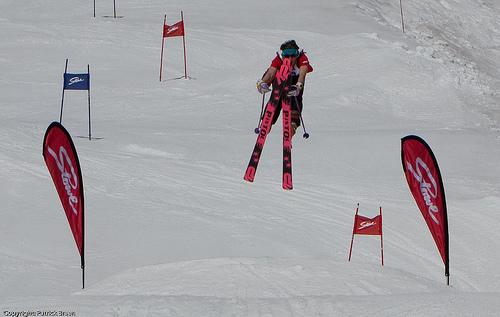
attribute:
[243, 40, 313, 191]
person — jumping, doing tricks, skiing, jumping in air, performing stunt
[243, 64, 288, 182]
ski — bright pink, pink, hot pink, black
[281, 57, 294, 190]
ski — bright pink, pink, hot pink, black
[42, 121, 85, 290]
flag — red advertisement, red, advertisement, saying stowe, white, tear-drop shaped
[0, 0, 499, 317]
snow — snowy, white, icy, icy white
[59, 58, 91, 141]
track advertisement — for skiing, blue, single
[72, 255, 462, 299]
pile — of snow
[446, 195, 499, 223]
pile — of snow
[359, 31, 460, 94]
pile — of snow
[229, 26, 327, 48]
pile — of snow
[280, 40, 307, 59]
hair — brown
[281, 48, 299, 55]
headband — blue, wide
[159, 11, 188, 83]
flag — red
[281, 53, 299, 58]
sunglasses — black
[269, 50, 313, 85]
shirt — red, white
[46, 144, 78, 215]
writing — white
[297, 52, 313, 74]
sleeve — red, short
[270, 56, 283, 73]
sleeve — short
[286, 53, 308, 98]
arm — straightened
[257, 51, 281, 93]
arm — straightened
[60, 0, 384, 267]
series — of ski gates